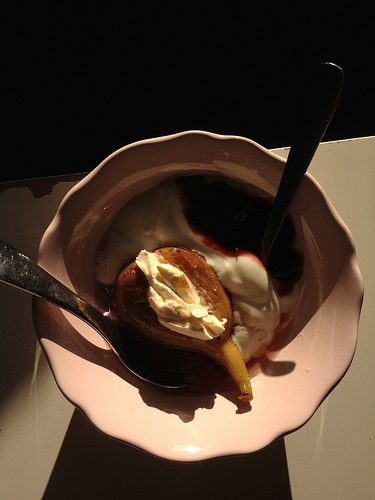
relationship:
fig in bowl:
[119, 245, 256, 405] [29, 125, 367, 465]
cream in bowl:
[133, 247, 227, 342] [29, 125, 367, 465]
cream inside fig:
[133, 247, 227, 342] [112, 241, 253, 400]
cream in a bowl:
[133, 247, 227, 342] [32, 128, 364, 464]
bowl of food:
[32, 145, 372, 440] [105, 222, 287, 389]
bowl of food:
[32, 128, 364, 464] [86, 201, 313, 447]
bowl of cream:
[32, 128, 364, 464] [133, 247, 227, 342]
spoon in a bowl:
[0, 243, 199, 391] [33, 126, 353, 498]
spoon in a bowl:
[246, 63, 357, 316] [33, 126, 353, 498]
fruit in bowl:
[95, 180, 281, 359] [29, 125, 367, 465]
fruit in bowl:
[104, 229, 277, 401] [32, 128, 364, 464]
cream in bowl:
[133, 247, 231, 341] [29, 125, 367, 465]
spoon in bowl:
[0, 243, 201, 391] [29, 125, 367, 465]